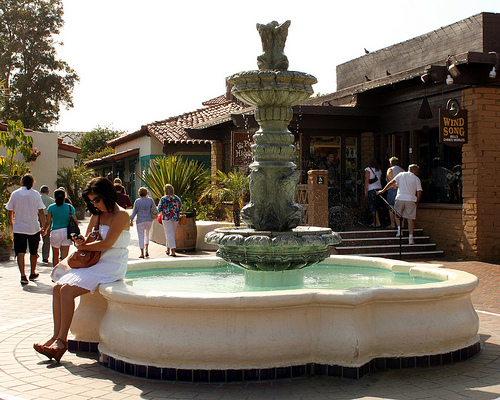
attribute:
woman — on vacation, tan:
[33, 175, 131, 365]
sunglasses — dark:
[89, 195, 99, 203]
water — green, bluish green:
[131, 260, 442, 289]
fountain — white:
[68, 20, 484, 379]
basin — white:
[68, 256, 480, 375]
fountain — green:
[205, 20, 339, 271]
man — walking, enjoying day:
[3, 174, 47, 287]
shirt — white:
[4, 186, 48, 234]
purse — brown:
[69, 215, 105, 268]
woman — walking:
[40, 189, 84, 265]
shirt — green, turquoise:
[46, 201, 77, 232]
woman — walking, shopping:
[157, 184, 186, 257]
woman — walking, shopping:
[125, 186, 161, 259]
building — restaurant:
[185, 26, 500, 259]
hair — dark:
[83, 176, 118, 214]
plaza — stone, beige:
[0, 208, 497, 398]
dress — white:
[52, 229, 131, 293]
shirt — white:
[393, 171, 422, 202]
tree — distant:
[1, 1, 80, 132]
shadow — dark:
[38, 336, 499, 396]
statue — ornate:
[253, 20, 292, 70]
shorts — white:
[50, 229, 70, 248]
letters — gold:
[442, 115, 465, 136]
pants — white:
[163, 219, 180, 250]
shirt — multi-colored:
[156, 195, 182, 219]